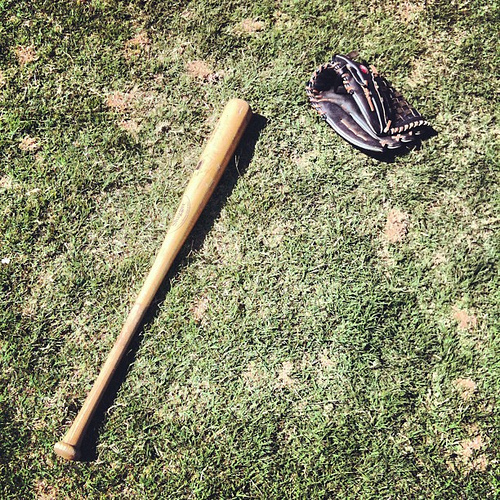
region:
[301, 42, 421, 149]
this is a baseball glove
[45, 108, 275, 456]
this is a baseball bat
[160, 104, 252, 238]
the bat is wooden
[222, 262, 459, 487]
this is the grass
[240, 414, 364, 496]
the grass is green in color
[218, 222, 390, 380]
the grass has several patches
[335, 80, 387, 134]
the glove is black in color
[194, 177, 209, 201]
the bat is brown in color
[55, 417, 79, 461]
this is the bat handle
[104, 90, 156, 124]
the patch is brown in color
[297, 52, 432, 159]
The black baseball glove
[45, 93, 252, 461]
The wood baseball bat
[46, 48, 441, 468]
The baseball equipment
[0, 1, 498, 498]
The grass that the baseball equipment is on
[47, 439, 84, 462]
The bottom handle of the bat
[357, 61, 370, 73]
The red label on the black glove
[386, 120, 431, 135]
The stitching on the end of the glove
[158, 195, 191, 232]
The label on the bat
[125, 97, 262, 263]
The barrel of the bat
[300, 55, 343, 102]
The the hand enters the glove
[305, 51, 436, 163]
The black baseball glove.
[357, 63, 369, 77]
Red label on the baseball glove.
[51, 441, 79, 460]
Bottom of the baseball bat.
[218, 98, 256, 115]
Tip of the baseball bat.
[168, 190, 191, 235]
Black design print on the baseball bat.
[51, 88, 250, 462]
Full length of the baseball bat.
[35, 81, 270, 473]
Grass area where the bat is laying.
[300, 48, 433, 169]
Grass area where the baseball glove is placed.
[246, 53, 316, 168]
Grass area between the bat and the baseball glove.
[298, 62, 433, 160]
Beige strings on the baseball gloves.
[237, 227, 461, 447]
The grass is green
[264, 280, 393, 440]
There are patches of brown in the grass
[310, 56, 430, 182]
There is a baseball glove.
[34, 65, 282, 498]
There is a baseball bat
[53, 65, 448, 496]
This picture is taken outside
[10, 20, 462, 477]
This picture is taken during the day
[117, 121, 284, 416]
The bat is brown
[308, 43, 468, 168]
The glove is black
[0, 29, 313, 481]
The bat is wood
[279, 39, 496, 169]
The glove is leather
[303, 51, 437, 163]
Baseball glove on grass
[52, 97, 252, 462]
Baseball bat on grass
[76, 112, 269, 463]
Baseball bat shadow on grass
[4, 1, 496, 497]
Grass is green with dirt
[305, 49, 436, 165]
Baseball glove is black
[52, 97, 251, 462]
Baseball glove is tan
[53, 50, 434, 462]
Baseball bat with glove on grass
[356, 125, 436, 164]
Shadow of baseball glove on grass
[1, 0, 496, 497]
Baseball bat and glove outside on grass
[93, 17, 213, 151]
Tan dirt in grass